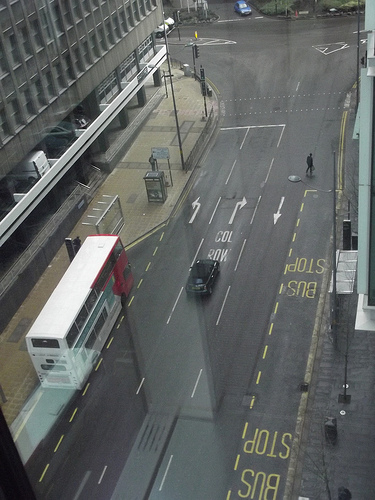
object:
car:
[184, 256, 222, 301]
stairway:
[73, 161, 111, 201]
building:
[0, 1, 168, 336]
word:
[286, 279, 317, 300]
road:
[24, 0, 368, 498]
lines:
[208, 195, 223, 225]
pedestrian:
[305, 152, 315, 178]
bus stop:
[95, 194, 126, 239]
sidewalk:
[0, 57, 221, 432]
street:
[19, 1, 369, 498]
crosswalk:
[219, 88, 350, 122]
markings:
[215, 285, 232, 326]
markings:
[234, 238, 247, 272]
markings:
[250, 195, 262, 226]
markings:
[190, 368, 203, 398]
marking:
[219, 122, 285, 149]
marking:
[264, 156, 275, 184]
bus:
[24, 235, 135, 392]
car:
[232, 0, 254, 18]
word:
[243, 427, 293, 459]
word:
[237, 468, 281, 500]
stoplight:
[192, 43, 200, 82]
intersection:
[169, 0, 366, 130]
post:
[161, 68, 170, 102]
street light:
[162, 16, 186, 172]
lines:
[224, 158, 237, 186]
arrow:
[188, 196, 202, 224]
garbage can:
[323, 413, 337, 447]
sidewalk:
[280, 69, 375, 498]